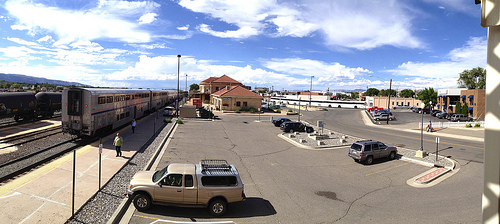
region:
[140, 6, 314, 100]
the sky is clear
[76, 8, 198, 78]
the sky is clear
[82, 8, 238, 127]
the sky is clear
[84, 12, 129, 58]
the sky is clear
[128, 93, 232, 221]
a truck parked on the street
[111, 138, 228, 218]
a truck parked in the lot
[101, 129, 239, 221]
a truck in the parking lot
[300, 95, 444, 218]
a suv parked in a lot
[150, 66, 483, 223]
vehicles parked in a parking lot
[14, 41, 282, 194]
train on the train tracks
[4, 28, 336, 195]
train tracks on a track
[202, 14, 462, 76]
clouds in the sky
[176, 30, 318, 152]
a building in the distance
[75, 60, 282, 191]
peopole walking on the sidewalk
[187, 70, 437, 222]
cars parked on lot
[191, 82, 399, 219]
large empty parking lot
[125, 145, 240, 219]
silver truck parked on lot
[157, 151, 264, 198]
racks put on top of truck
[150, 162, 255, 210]
add on to back of truck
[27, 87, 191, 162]
silver train on tracks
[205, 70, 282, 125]
train station in background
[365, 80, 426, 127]
another parking lot with cars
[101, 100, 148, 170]
people standing on train platform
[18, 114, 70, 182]
train tracks by train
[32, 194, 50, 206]
white line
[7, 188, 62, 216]
white line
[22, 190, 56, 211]
white line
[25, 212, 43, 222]
white line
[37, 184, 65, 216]
white line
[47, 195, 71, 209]
white line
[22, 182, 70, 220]
white line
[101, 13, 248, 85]
the sky is clear and blue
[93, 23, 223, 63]
the sky is clear and blue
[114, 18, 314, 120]
the sky is clear and blue